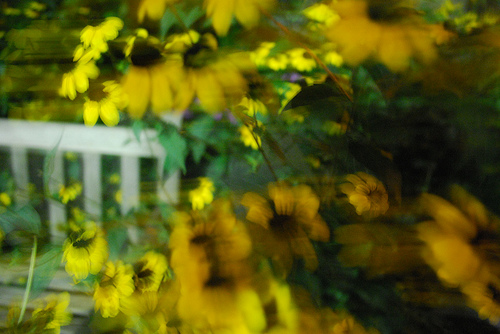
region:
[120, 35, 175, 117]
yellow flower on bush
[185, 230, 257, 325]
yellow flower on bush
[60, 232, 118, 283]
yellow flower on bush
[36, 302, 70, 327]
yellow flower on bush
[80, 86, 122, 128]
yellow flower on bush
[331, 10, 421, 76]
yellow flower on bush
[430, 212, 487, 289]
yellow flower on bush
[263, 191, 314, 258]
yellow flower on bush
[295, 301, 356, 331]
yellow flower on bush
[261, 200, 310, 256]
yellow flower on bush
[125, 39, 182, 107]
yellow black eyed susie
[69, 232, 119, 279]
yellow black eyed susie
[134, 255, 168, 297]
yellow black eyed susie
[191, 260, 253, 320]
yellow black eyed susie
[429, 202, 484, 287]
yellow black eyed susie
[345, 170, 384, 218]
yellow black eyed susie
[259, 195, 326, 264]
yellow black eyed susie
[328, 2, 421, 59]
yellow black eyed susie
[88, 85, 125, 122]
yellow black eyed susie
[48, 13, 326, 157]
beautiful yellow flower in tree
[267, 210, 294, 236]
red part in the flower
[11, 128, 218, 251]
a small white gate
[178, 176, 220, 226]
a part of the flower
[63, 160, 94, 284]
a small gap in gate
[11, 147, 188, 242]
a series of wood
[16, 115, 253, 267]
a small wooden gate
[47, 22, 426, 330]
a group of flowers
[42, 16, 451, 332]
a bunch of yellow flowers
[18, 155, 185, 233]
gap in between wood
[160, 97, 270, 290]
the flowers are yellow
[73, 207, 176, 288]
the flowers are yellow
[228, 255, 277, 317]
the flowers are yellow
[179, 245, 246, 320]
the flowers are yellow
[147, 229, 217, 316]
the flowers are yellow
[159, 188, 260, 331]
the flowers are yellow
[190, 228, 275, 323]
the flowers are yellow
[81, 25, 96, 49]
a yellow petal on the flower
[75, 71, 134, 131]
a yellow flower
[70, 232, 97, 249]
the black center of a flower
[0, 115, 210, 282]
a white wooden fence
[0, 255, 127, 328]
a wooden floor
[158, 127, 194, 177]
a green leaf on the plant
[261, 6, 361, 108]
the stem of a flower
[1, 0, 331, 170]
a reflection on the glass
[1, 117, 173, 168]
a white railing